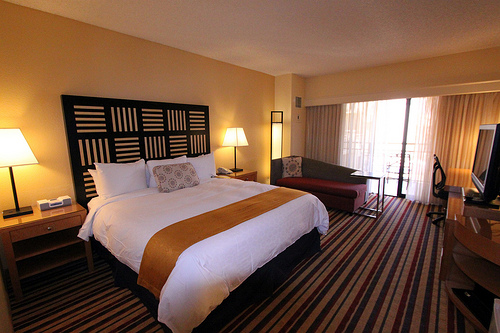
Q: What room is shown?
A: Bedroom.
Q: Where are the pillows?
A: On the bed.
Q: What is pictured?
A: Hotel room.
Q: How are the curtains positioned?
A: Open.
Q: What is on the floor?
A: Carpet.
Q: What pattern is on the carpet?
A: Stripes.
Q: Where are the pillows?
A: On the bed.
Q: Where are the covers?
A: On the bed.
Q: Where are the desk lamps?
A: On the night stands.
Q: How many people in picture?
A: None.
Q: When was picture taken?
A: During daylight.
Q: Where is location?
A: In a hotel.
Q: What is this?
A: A bedroom.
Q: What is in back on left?
A: A sofa.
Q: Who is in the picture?
A: No one.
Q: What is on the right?
A: A t.v.